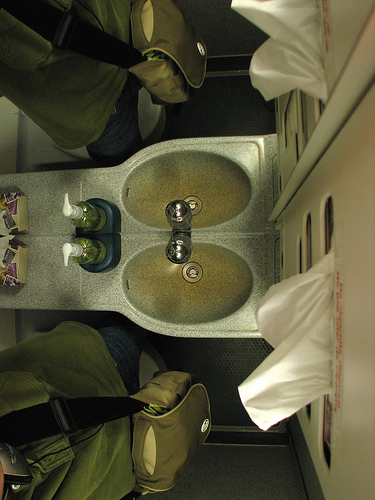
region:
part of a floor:
[232, 461, 248, 484]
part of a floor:
[255, 451, 270, 462]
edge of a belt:
[92, 400, 129, 442]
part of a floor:
[237, 445, 256, 465]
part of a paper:
[245, 388, 287, 449]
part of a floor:
[225, 465, 246, 488]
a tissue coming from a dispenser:
[282, 183, 358, 459]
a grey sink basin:
[118, 240, 256, 325]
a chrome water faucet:
[165, 238, 195, 263]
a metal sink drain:
[184, 262, 203, 285]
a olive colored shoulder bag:
[70, 362, 214, 487]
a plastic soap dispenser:
[55, 232, 120, 275]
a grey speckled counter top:
[31, 241, 72, 304]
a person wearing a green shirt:
[1, 340, 131, 496]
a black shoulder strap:
[4, 388, 142, 442]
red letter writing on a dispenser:
[331, 249, 352, 421]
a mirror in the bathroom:
[2, 99, 273, 227]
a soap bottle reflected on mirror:
[52, 189, 123, 234]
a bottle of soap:
[57, 231, 124, 279]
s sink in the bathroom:
[116, 233, 275, 348]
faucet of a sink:
[163, 239, 193, 270]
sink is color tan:
[29, 237, 281, 343]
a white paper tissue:
[237, 240, 329, 429]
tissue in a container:
[232, 246, 331, 426]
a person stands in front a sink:
[1, 313, 217, 498]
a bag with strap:
[7, 371, 221, 497]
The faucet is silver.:
[158, 238, 197, 263]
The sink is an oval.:
[112, 237, 267, 322]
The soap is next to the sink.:
[53, 234, 106, 268]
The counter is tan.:
[21, 237, 266, 328]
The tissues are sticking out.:
[261, 241, 337, 414]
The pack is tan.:
[134, 378, 211, 488]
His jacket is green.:
[6, 336, 137, 499]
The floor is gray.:
[172, 341, 290, 422]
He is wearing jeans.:
[104, 329, 149, 389]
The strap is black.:
[13, 390, 150, 432]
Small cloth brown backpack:
[126, 371, 212, 495]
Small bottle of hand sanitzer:
[59, 235, 107, 263]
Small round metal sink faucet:
[166, 234, 192, 264]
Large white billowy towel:
[237, 245, 331, 429]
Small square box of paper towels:
[0, 235, 28, 284]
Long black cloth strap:
[1, 393, 146, 444]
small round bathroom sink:
[119, 241, 254, 324]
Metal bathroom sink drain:
[182, 259, 204, 280]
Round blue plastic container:
[75, 234, 121, 272]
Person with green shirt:
[2, 319, 141, 497]